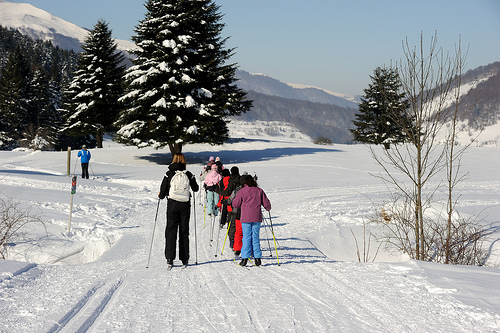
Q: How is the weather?
A: Clear.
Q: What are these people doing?
A: Skiing.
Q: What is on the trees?
A: Snow.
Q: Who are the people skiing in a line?
A: Children.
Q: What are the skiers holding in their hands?
A: Ski poles.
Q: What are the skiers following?
A: A trail.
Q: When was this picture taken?
A: During the day.